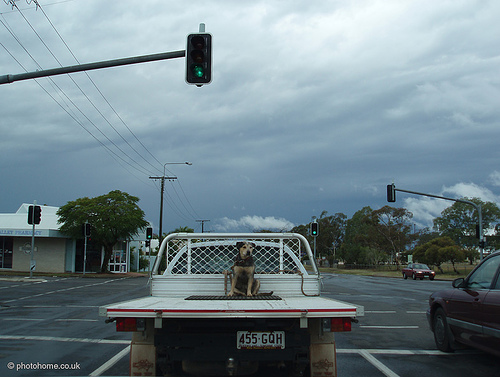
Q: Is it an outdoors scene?
A: Yes, it is outdoors.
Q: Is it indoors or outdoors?
A: It is outdoors.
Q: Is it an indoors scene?
A: No, it is outdoors.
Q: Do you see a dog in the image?
A: Yes, there is a dog.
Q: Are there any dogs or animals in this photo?
A: Yes, there is a dog.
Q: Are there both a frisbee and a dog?
A: No, there is a dog but no frisbees.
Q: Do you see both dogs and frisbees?
A: No, there is a dog but no frisbees.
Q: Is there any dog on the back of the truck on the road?
A: Yes, there is a dog on the back of the truck.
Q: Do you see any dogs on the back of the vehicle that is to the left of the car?
A: Yes, there is a dog on the back of the truck.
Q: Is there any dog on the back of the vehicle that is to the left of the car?
A: Yes, there is a dog on the back of the truck.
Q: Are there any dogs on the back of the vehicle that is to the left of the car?
A: Yes, there is a dog on the back of the truck.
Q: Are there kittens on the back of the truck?
A: No, there is a dog on the back of the truck.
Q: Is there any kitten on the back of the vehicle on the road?
A: No, there is a dog on the back of the truck.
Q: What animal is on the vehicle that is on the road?
A: The dog is on the truck.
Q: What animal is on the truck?
A: The dog is on the truck.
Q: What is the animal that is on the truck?
A: The animal is a dog.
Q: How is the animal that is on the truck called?
A: The animal is a dog.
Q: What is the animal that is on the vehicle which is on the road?
A: The animal is a dog.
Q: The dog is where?
A: The dog is on the truck.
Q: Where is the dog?
A: The dog is on the truck.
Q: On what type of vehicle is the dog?
A: The dog is on the truck.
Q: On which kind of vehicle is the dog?
A: The dog is on the truck.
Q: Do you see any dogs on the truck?
A: Yes, there is a dog on the truck.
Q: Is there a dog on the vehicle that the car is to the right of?
A: Yes, there is a dog on the truck.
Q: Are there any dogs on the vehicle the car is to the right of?
A: Yes, there is a dog on the truck.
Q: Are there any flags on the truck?
A: No, there is a dog on the truck.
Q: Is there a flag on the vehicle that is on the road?
A: No, there is a dog on the truck.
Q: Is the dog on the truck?
A: Yes, the dog is on the truck.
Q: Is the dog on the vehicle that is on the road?
A: Yes, the dog is on the truck.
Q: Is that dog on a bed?
A: No, the dog is on the truck.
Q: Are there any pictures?
A: No, there are no pictures.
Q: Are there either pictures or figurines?
A: No, there are no pictures or figurines.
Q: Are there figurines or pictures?
A: No, there are no pictures or figurines.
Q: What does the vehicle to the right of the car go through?
A: The vehicle goes through the intersection.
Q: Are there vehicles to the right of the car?
A: Yes, there is a vehicle to the right of the car.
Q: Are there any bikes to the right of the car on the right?
A: No, there is a vehicle to the right of the car.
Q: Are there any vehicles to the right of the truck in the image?
A: Yes, there is a vehicle to the right of the truck.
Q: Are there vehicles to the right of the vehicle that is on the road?
A: Yes, there is a vehicle to the right of the truck.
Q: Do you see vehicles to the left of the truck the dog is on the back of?
A: No, the vehicle is to the right of the truck.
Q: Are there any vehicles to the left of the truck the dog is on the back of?
A: No, the vehicle is to the right of the truck.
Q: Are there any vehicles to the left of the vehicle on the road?
A: No, the vehicle is to the right of the truck.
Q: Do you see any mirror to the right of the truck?
A: No, there is a vehicle to the right of the truck.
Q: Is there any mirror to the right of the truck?
A: No, there is a vehicle to the right of the truck.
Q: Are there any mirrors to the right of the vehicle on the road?
A: No, there is a vehicle to the right of the truck.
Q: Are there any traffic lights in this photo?
A: Yes, there is a traffic light.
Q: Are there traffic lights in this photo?
A: Yes, there is a traffic light.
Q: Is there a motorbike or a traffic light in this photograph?
A: Yes, there is a traffic light.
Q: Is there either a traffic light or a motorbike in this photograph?
A: Yes, there is a traffic light.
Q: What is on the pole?
A: The signal light is on the pole.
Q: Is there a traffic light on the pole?
A: Yes, there is a traffic light on the pole.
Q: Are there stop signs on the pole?
A: No, there is a traffic light on the pole.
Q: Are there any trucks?
A: Yes, there is a truck.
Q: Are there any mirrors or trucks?
A: Yes, there is a truck.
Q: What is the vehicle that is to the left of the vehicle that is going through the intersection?
A: The vehicle is a truck.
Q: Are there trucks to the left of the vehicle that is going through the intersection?
A: Yes, there is a truck to the left of the vehicle.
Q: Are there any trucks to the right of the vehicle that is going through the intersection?
A: No, the truck is to the left of the vehicle.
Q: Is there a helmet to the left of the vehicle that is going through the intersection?
A: No, there is a truck to the left of the vehicle.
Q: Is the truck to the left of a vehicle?
A: Yes, the truck is to the left of a vehicle.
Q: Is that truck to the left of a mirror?
A: No, the truck is to the left of a vehicle.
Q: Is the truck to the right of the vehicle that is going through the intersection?
A: No, the truck is to the left of the vehicle.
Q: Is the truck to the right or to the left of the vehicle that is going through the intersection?
A: The truck is to the left of the vehicle.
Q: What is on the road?
A: The truck is on the road.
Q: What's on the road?
A: The truck is on the road.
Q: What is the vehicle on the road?
A: The vehicle is a truck.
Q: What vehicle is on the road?
A: The vehicle is a truck.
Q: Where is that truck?
A: The truck is on the road.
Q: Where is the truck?
A: The truck is on the road.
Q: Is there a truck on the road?
A: Yes, there is a truck on the road.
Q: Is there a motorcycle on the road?
A: No, there is a truck on the road.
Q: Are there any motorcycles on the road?
A: No, there is a truck on the road.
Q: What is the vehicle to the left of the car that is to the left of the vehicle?
A: The vehicle is a truck.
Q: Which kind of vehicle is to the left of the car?
A: The vehicle is a truck.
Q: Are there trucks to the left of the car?
A: Yes, there is a truck to the left of the car.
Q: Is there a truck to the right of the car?
A: No, the truck is to the left of the car.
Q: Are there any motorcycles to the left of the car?
A: No, there is a truck to the left of the car.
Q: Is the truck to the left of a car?
A: Yes, the truck is to the left of a car.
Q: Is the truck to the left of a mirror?
A: No, the truck is to the left of a car.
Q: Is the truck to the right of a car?
A: No, the truck is to the left of a car.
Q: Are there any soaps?
A: No, there are no soaps.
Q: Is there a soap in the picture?
A: No, there are no soaps.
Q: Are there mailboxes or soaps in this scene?
A: No, there are no soaps or mailboxes.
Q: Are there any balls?
A: No, there are no balls.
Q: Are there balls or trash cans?
A: No, there are no balls or trash cans.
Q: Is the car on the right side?
A: Yes, the car is on the right of the image.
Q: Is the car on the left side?
A: No, the car is on the right of the image.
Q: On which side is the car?
A: The car is on the right of the image.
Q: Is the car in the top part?
A: No, the car is in the bottom of the image.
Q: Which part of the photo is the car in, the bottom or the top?
A: The car is in the bottom of the image.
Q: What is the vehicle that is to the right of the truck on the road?
A: The vehicle is a car.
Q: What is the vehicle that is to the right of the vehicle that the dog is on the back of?
A: The vehicle is a car.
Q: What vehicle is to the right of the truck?
A: The vehicle is a car.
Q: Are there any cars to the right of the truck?
A: Yes, there is a car to the right of the truck.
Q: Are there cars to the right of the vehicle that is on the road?
A: Yes, there is a car to the right of the truck.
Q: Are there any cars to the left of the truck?
A: No, the car is to the right of the truck.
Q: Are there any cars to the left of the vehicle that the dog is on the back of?
A: No, the car is to the right of the truck.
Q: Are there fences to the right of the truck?
A: No, there is a car to the right of the truck.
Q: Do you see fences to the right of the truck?
A: No, there is a car to the right of the truck.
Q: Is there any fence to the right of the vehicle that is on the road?
A: No, there is a car to the right of the truck.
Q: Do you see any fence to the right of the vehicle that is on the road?
A: No, there is a car to the right of the truck.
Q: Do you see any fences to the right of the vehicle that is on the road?
A: No, there is a car to the right of the truck.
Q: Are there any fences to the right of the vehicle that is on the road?
A: No, there is a car to the right of the truck.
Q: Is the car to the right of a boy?
A: No, the car is to the right of a truck.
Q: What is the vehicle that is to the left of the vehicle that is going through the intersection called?
A: The vehicle is a car.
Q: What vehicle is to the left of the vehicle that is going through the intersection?
A: The vehicle is a car.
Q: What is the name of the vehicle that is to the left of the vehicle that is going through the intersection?
A: The vehicle is a car.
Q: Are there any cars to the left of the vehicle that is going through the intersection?
A: Yes, there is a car to the left of the vehicle.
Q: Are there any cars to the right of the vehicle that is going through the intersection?
A: No, the car is to the left of the vehicle.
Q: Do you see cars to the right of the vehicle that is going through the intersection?
A: No, the car is to the left of the vehicle.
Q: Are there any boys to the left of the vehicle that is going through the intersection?
A: No, there is a car to the left of the vehicle.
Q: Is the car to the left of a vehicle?
A: Yes, the car is to the left of a vehicle.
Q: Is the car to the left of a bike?
A: No, the car is to the left of a vehicle.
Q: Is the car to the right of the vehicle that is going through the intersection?
A: No, the car is to the left of the vehicle.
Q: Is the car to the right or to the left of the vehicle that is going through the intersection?
A: The car is to the left of the vehicle.